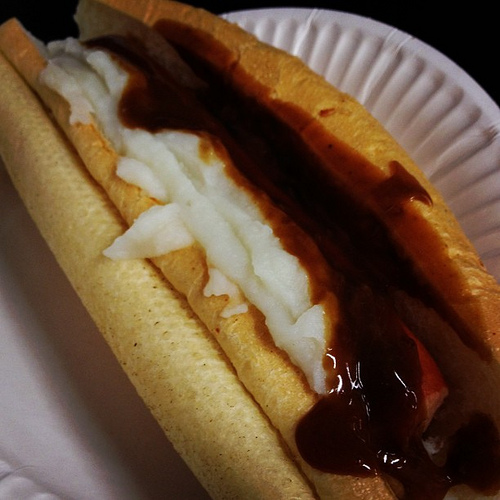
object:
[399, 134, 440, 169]
ground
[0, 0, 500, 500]
bun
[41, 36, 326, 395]
onions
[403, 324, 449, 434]
hot dog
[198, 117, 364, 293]
potatoes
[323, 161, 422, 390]
gravy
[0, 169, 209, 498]
shadow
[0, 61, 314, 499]
spots